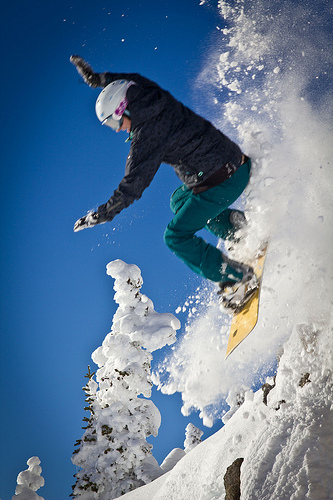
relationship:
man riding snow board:
[68, 53, 257, 313] [226, 238, 265, 342]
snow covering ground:
[243, 383, 331, 499] [215, 373, 308, 498]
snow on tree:
[127, 278, 192, 378] [70, 259, 181, 498]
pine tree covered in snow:
[67, 364, 105, 499] [92, 256, 177, 491]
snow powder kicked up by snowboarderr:
[249, 95, 331, 281] [69, 51, 253, 297]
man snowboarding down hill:
[58, 53, 261, 287] [80, 328, 324, 492]